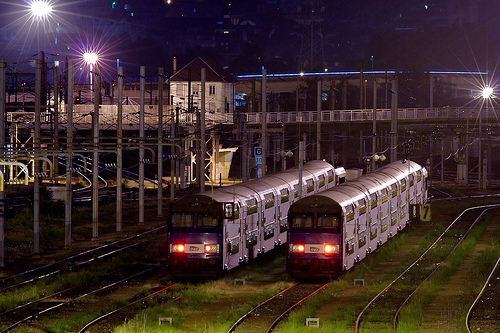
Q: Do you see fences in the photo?
A: Yes, there is a fence.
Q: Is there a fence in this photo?
A: Yes, there is a fence.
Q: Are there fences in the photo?
A: Yes, there is a fence.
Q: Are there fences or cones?
A: Yes, there is a fence.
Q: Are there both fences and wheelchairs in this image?
A: No, there is a fence but no wheelchairs.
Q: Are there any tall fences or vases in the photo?
A: Yes, there is a tall fence.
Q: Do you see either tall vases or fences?
A: Yes, there is a tall fence.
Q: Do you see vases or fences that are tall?
A: Yes, the fence is tall.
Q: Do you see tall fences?
A: Yes, there is a tall fence.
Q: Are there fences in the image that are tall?
A: Yes, there is a fence that is tall.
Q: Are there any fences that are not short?
A: Yes, there is a tall fence.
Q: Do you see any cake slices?
A: No, there are no cake slices.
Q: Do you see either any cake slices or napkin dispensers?
A: No, there are no cake slices or napkin dispensers.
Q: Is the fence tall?
A: Yes, the fence is tall.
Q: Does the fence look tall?
A: Yes, the fence is tall.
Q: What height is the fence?
A: The fence is tall.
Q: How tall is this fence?
A: The fence is tall.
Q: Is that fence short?
A: No, the fence is tall.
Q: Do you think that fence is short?
A: No, the fence is tall.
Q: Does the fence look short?
A: No, the fence is tall.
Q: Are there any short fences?
A: No, there is a fence but it is tall.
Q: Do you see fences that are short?
A: No, there is a fence but it is tall.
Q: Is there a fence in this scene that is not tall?
A: No, there is a fence but it is tall.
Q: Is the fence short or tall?
A: The fence is tall.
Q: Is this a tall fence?
A: Yes, this is a tall fence.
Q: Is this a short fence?
A: No, this is a tall fence.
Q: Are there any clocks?
A: No, there are no clocks.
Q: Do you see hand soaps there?
A: No, there are no hand soaps.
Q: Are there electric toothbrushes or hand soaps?
A: No, there are no hand soaps or electric toothbrushes.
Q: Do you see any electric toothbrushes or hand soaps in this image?
A: No, there are no hand soaps or electric toothbrushes.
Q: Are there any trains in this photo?
A: Yes, there is a train.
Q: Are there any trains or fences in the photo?
A: Yes, there is a train.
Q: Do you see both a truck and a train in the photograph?
A: No, there is a train but no trucks.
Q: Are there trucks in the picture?
A: No, there are no trucks.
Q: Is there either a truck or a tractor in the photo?
A: No, there are no trucks or tractors.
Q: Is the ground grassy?
A: Yes, the ground is grassy.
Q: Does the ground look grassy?
A: Yes, the ground is grassy.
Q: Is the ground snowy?
A: No, the ground is grassy.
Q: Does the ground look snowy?
A: No, the ground is grassy.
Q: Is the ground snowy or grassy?
A: The ground is grassy.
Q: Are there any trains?
A: Yes, there is a train.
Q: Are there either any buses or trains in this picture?
A: Yes, there is a train.